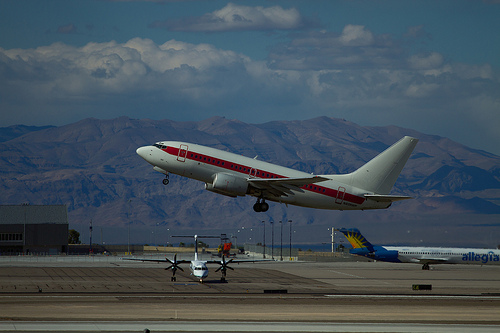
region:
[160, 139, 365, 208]
red stripe on an airplane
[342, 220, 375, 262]
blue and yellow tail on an airplane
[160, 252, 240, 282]
two propellors on an airplane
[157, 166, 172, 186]
front landing gear tire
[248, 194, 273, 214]
double back tires of landing gear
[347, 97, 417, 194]
white tail of an airplane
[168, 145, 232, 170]
windows on an airplane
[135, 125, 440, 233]
airplane taking off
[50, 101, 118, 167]
hilly mountains in the distance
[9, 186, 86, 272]
building at an airport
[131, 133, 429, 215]
Airplane taking off from runway.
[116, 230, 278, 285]
Airplane taxiing out to runway.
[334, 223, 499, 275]
Airplane parked on tarmac.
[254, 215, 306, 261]
Lights standing along parking area.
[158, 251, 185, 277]
Propeller in front of engine.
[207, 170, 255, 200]
Jet engine mounted under plane's wing.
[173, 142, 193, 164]
Front passenger door on plane.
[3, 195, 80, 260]
Portion of airplane hangar.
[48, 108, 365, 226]
Mountains rising in background.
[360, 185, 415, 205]
Rear horizontal stabilizer on plane.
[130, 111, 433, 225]
White and red plane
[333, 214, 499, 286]
White and blue plane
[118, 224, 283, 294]
Small white plane on ground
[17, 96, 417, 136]
Tall brown mountian tops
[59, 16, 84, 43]
White clouds in the sky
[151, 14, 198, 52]
White clouds in the sky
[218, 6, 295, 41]
White clouds in the sky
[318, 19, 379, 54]
White clouds in the sky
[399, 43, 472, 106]
White clouds in the sky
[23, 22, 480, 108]
White clouds in the sky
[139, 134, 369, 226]
this is a jet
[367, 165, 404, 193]
the jet is black in color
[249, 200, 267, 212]
this is the wheel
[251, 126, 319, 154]
this is the mountain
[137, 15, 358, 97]
this is the sky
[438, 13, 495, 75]
the sky is blue in color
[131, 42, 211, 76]
these are the clouds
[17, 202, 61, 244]
this is a building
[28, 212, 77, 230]
this is the roof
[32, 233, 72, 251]
this is the wall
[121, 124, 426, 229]
the plane is red and white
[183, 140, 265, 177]
windows are on the plane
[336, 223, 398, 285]
the tail is blue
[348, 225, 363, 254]
yellow sunlight is on the tail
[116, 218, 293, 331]
the plane has two propellers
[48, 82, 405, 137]
the hill is in the background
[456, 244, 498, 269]
allegia is the make of the plane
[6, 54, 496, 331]
the scene is at the airport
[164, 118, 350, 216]
the doors are three in total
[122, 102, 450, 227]
the plane is taking off